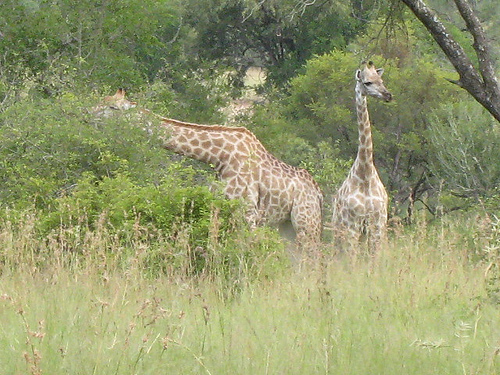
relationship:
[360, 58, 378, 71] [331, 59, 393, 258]
hairy horns on giraffe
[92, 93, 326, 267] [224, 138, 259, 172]
giraffe has brown spots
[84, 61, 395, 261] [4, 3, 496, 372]
giraffes in field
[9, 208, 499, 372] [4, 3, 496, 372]
grass in feild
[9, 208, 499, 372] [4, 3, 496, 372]
grass in field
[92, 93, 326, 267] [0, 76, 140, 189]
giraffe eating small tree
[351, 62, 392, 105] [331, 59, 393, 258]
head of giraffe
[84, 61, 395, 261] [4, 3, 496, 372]
giraffes out in field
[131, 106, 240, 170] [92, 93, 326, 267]
neck of giraffe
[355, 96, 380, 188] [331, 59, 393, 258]
neck of giraffe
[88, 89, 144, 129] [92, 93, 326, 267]
head of giraffe